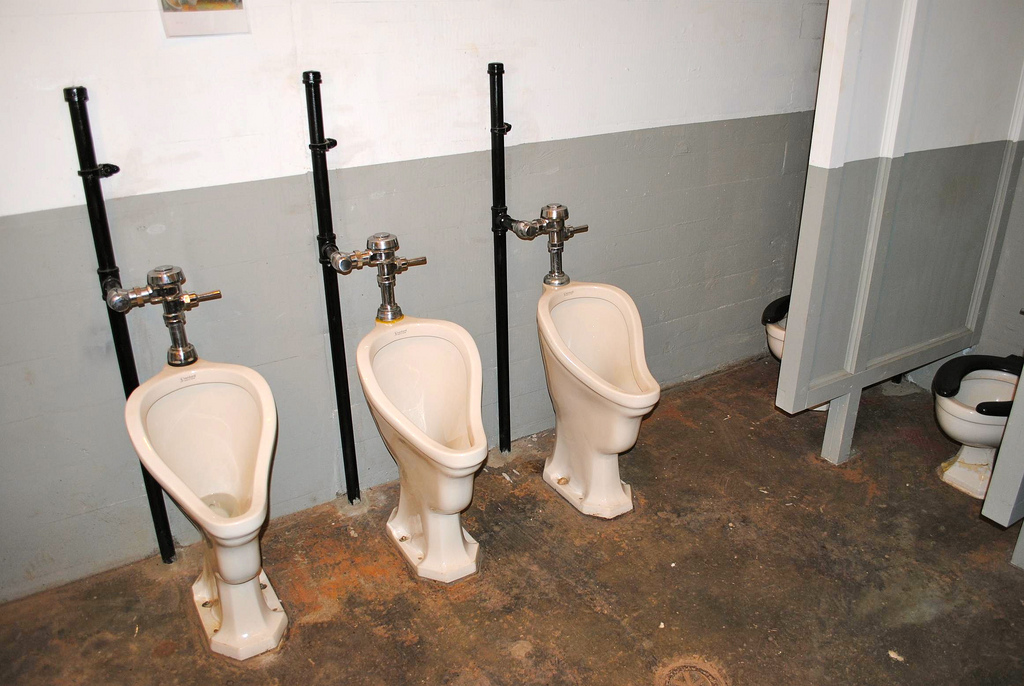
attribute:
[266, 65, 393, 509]
pipe — black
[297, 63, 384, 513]
pipe — black, metal